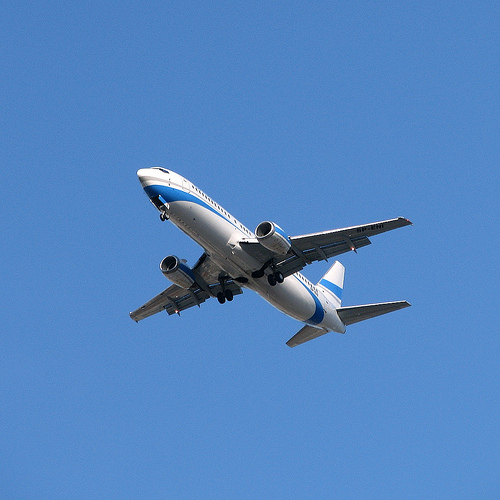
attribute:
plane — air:
[109, 141, 426, 361]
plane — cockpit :
[25, 125, 475, 361]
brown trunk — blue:
[343, 22, 477, 124]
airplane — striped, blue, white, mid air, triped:
[129, 160, 411, 349]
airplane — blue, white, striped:
[113, 155, 424, 370]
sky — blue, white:
[249, 22, 331, 77]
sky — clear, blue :
[1, 6, 497, 498]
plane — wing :
[122, 160, 414, 362]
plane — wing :
[126, 149, 420, 354]